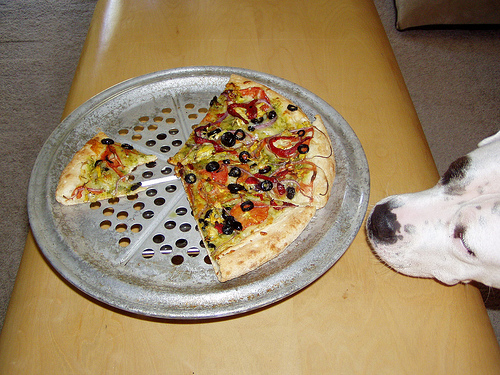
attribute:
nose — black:
[371, 202, 397, 243]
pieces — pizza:
[168, 73, 333, 286]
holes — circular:
[141, 207, 155, 223]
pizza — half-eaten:
[48, 120, 166, 210]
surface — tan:
[13, 7, 478, 372]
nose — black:
[362, 196, 403, 243]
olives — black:
[246, 164, 302, 200]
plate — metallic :
[15, 54, 375, 330]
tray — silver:
[13, 57, 378, 333]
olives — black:
[215, 206, 245, 236]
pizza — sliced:
[170, 66, 346, 289]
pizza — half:
[53, 121, 158, 208]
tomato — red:
[222, 195, 272, 225]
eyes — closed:
[456, 225, 476, 255]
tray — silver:
[87, 214, 182, 286]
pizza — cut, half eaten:
[63, 128, 153, 200]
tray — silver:
[84, 227, 186, 294]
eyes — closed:
[444, 160, 481, 263]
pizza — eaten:
[68, 133, 153, 204]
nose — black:
[369, 204, 405, 247]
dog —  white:
[370, 195, 484, 265]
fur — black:
[459, 156, 470, 167]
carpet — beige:
[22, 54, 57, 93]